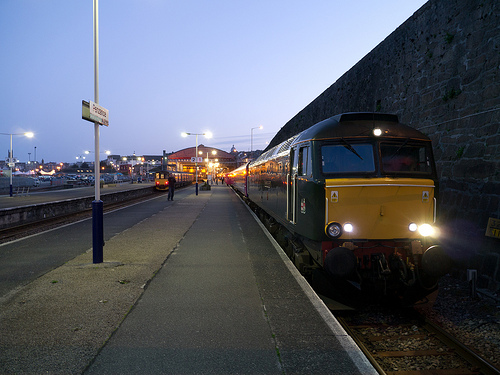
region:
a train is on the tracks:
[222, 112, 449, 289]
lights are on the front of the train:
[321, 116, 439, 272]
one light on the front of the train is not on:
[323, 216, 342, 243]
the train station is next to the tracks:
[157, 140, 239, 187]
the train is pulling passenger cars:
[225, 113, 447, 279]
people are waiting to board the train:
[209, 167, 238, 204]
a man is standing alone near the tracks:
[160, 172, 180, 204]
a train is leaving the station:
[152, 165, 202, 192]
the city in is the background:
[1, 143, 263, 210]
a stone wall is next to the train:
[256, 44, 499, 364]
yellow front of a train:
[315, 177, 440, 246]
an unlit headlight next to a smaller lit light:
[327, 219, 361, 244]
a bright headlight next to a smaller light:
[405, 220, 439, 242]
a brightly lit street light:
[177, 122, 219, 152]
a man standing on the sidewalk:
[156, 173, 183, 203]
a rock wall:
[399, 31, 497, 126]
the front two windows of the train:
[316, 121, 455, 185]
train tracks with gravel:
[351, 320, 493, 373]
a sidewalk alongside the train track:
[129, 275, 302, 372]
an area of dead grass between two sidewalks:
[35, 279, 99, 349]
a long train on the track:
[215, 112, 444, 293]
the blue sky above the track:
[1, 1, 416, 143]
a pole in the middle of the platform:
[78, 2, 120, 264]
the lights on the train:
[323, 218, 441, 243]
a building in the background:
[159, 135, 231, 177]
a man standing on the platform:
[162, 170, 174, 200]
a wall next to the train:
[263, 2, 495, 239]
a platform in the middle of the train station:
[10, 180, 340, 374]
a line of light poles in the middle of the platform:
[180, 118, 223, 197]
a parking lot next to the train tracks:
[3, 167, 125, 189]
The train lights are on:
[317, 202, 450, 277]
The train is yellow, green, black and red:
[211, 109, 453, 287]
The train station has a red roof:
[141, 115, 236, 190]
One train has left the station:
[126, 107, 463, 328]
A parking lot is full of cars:
[20, 137, 150, 216]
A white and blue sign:
[68, 54, 128, 289]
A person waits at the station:
[216, 170, 233, 196]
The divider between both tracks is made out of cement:
[43, 167, 342, 369]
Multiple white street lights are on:
[6, 115, 258, 212]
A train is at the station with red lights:
[143, 142, 201, 218]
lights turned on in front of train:
[322, 214, 447, 244]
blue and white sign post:
[78, 0, 108, 266]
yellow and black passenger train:
[224, 109, 446, 308]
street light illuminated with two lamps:
[176, 122, 213, 194]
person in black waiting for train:
[164, 170, 177, 200]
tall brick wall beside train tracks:
[411, 2, 495, 254]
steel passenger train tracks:
[333, 307, 498, 373]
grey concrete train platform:
[86, 269, 378, 370]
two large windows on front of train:
[316, 135, 436, 177]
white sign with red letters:
[78, 97, 110, 127]